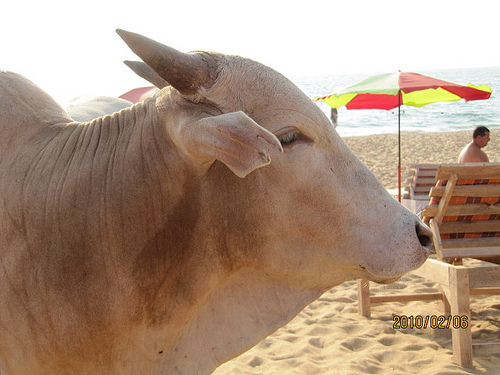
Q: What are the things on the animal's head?
A: Horns.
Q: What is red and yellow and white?
A: A beach umbrella.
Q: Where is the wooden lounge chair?
A: On the sand, between the animal and the umbrella.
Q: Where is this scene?
A: At the beach.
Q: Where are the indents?
A: On the sand.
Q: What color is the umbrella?
A: Red white yellow.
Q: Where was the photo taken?
A: Beach.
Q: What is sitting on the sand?
A: Chair.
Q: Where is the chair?
A: On the beach.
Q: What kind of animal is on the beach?
A: Cow.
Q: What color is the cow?
A: Brown.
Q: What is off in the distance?
A: Water.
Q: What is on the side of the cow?
A: Ear.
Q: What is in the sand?
A: Footprints.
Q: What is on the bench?
A: A man.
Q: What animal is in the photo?
A: Cow.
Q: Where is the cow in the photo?
A: Beach.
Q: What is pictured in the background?
A: An umbrella.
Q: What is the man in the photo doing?
A: Sitting on a chair.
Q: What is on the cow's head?
A: Horns.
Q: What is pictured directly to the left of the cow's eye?
A: Ear.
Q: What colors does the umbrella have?
A: Red, green and yellow.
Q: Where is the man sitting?
A: Under the umbrella.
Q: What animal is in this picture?
A: A bull.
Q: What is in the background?
A: The ocean.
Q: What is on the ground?
A: Sand.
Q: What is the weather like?
A: Sunny.